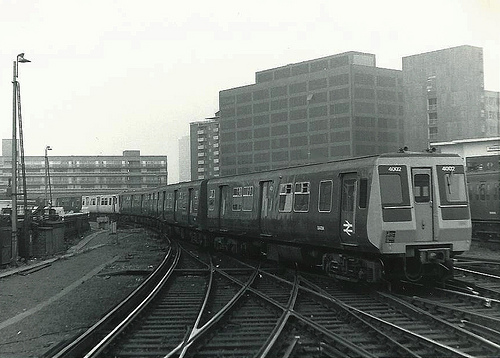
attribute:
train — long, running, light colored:
[55, 154, 471, 288]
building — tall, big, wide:
[402, 44, 500, 153]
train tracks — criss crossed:
[50, 239, 500, 355]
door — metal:
[412, 167, 435, 243]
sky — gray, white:
[1, 2, 497, 185]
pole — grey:
[14, 51, 26, 267]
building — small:
[189, 113, 221, 181]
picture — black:
[1, 7, 498, 357]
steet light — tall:
[12, 52, 30, 269]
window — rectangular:
[328, 73, 351, 85]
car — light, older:
[206, 151, 472, 254]